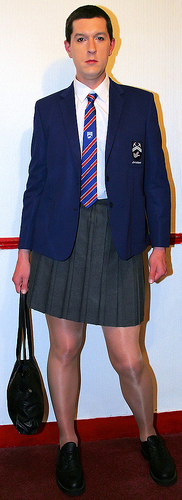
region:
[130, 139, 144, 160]
black emblem on front of suit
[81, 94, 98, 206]
red and blue neck tie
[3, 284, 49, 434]
black purse being held by man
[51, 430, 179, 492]
pair of black shoes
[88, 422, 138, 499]
red carpet on room floor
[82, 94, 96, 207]
Red and blue striped tie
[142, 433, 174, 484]
Black shoe on a person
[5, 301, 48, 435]
Black purse in a person's hand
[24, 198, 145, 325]
Dark gray pleated skirt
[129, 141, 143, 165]
Logo on a blazer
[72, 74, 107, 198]
White shirt on a person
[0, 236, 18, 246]
Red painted strip on wall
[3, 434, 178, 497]
Carpet under person's feet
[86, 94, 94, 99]
red stripe on tie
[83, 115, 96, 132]
red stripe on tie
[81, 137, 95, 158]
red stripe on tie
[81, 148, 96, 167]
red stripe on tie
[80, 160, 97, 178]
red stripe on tie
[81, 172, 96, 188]
red stripe on tie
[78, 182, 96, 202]
red stripe on tie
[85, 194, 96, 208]
red stripe on tie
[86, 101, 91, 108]
red stripe on tie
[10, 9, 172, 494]
man wearing pantyhose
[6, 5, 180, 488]
man carrying a black purse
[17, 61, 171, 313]
uniform has blue and white striped tie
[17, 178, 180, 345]
uniform has grey skirt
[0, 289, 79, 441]
carrying large black purse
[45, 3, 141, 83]
man wearing makeup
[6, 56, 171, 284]
man wearing blue blaxer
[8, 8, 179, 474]
man posing for photo in school uniform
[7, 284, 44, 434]
A black purse a man is holding.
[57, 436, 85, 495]
A man's right black shoe.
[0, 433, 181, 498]
Maroon carpet a man is standing on.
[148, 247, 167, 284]
A man's left hand.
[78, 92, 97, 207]
A blue and red striped tie.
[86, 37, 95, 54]
Nose on a man's face.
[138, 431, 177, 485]
A man's left black shoe.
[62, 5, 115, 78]
Head of a man with black hair.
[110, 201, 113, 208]
Bottom black button on a coat.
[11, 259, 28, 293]
A man's right hand.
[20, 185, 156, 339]
An article of clothing.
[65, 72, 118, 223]
An article of clothing.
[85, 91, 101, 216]
An article of clothing.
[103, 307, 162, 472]
An article of clothing.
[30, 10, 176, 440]
A person is standing up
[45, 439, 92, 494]
An article of clothing.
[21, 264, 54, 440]
An article of clothing.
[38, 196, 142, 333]
An article of clothing.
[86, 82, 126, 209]
An article of clothing.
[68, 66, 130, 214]
An article of clothing.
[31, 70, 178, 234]
An article of clothing.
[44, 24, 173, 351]
An article of clothing.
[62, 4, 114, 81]
man with black short hair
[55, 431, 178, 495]
one pair of black shoes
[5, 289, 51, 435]
a black shoulder bag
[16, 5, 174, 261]
boy in a blue blazer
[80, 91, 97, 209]
a red, white and blue striped tie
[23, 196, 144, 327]
a grey pleated skirt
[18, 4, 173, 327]
man wearing a skirt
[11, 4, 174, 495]
man dressed at a woman